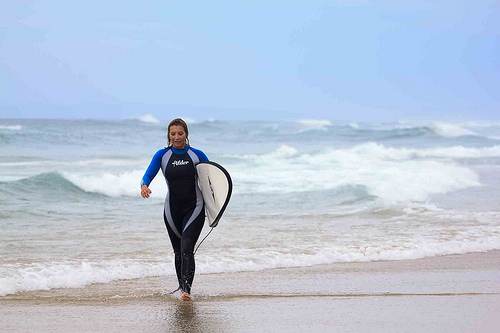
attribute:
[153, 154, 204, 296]
wetsuit — black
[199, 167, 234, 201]
logo — black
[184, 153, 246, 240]
surfboard — black, white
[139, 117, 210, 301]
wet suit — tricolored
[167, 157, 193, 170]
print — white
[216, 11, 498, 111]
sky — blue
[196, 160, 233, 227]
surfboard — white, trimmed, black trimmed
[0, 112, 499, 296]
water — white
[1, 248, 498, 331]
beach — sandy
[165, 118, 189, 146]
hair — wet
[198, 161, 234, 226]
edge — black